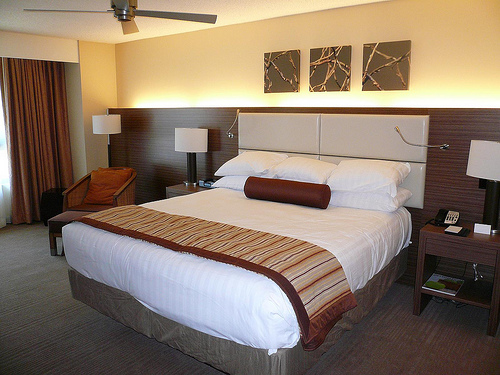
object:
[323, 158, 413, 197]
pillow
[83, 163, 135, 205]
pillows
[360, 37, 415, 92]
painting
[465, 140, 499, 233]
lamp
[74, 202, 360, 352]
blanket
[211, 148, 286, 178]
pillow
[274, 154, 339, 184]
pillow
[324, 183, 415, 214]
pillow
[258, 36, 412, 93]
three decorative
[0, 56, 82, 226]
curtains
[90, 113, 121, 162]
lamp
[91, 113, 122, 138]
shade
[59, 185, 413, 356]
coverlet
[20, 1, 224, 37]
fan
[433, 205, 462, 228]
telephone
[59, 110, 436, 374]
bed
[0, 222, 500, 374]
carpet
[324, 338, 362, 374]
lines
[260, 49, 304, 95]
art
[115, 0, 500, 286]
wall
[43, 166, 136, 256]
chair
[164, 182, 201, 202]
table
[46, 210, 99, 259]
foot rest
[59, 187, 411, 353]
sheet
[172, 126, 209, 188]
lamp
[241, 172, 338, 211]
pillow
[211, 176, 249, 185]
pillow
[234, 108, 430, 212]
headboard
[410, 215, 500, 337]
bedside table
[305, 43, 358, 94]
painting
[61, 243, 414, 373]
skirting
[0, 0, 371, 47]
ceiling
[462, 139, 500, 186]
shade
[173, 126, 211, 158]
shade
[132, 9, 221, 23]
blades